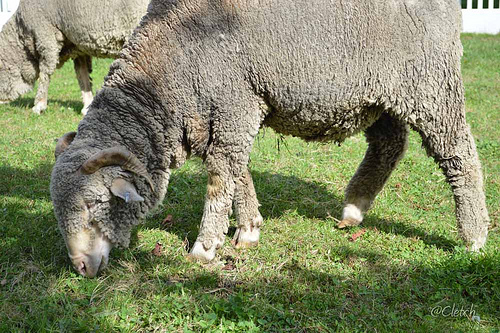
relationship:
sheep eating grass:
[52, 1, 491, 276] [4, 32, 498, 332]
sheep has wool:
[52, 1, 491, 276] [85, 0, 474, 198]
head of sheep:
[47, 126, 167, 277] [52, 1, 491, 276]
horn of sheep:
[81, 146, 155, 190] [52, 1, 491, 276]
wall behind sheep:
[458, 0, 500, 33] [52, 1, 491, 276]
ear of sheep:
[108, 177, 144, 205] [52, 1, 491, 276]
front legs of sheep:
[191, 154, 262, 262] [52, 1, 491, 276]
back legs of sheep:
[342, 111, 490, 249] [52, 1, 491, 276]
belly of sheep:
[268, 99, 374, 145] [52, 1, 491, 276]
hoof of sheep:
[188, 228, 263, 261] [52, 1, 491, 276]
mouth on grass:
[88, 255, 109, 276] [4, 32, 498, 332]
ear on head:
[108, 177, 144, 205] [47, 126, 167, 277]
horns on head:
[53, 130, 157, 191] [47, 126, 167, 277]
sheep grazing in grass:
[52, 1, 491, 276] [4, 32, 498, 332]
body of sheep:
[179, 2, 463, 136] [52, 1, 491, 276]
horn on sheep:
[81, 146, 155, 190] [52, 1, 491, 276]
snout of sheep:
[59, 229, 113, 277] [52, 1, 491, 276]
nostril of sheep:
[79, 263, 86, 272] [52, 1, 491, 276]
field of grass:
[5, 31, 499, 333] [4, 32, 498, 332]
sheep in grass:
[52, 1, 491, 276] [4, 32, 498, 332]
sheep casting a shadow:
[52, 1, 491, 276] [5, 164, 453, 323]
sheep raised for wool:
[52, 1, 491, 276] [85, 0, 474, 198]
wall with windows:
[458, 0, 500, 33] [460, 0, 498, 10]